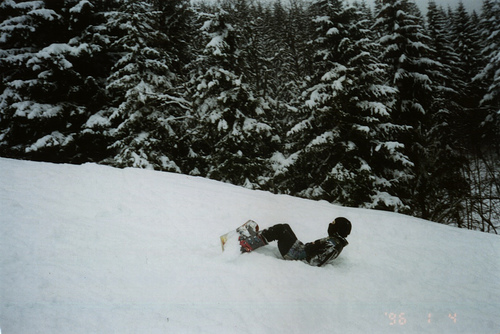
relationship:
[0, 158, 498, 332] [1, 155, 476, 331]
snow on hill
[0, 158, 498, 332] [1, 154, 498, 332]
snow on hill side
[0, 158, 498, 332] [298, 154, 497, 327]
snow on hill side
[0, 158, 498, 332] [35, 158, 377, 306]
snow on hillside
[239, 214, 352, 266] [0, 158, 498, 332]
person snowboarding in snow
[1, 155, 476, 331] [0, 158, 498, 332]
hill covered in snow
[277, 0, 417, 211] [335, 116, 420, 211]
tree covered in snow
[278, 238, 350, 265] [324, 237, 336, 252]
snow jacket covered in snow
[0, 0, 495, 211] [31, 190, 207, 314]
trees covered in snow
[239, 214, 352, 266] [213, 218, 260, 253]
person on board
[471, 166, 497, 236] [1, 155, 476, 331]
branches on hill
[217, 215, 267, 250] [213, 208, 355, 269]
skis on skier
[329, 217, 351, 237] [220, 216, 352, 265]
hat on skier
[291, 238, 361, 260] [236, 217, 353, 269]
snow jacket on skier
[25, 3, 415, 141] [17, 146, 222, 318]
evergreen trees bordering slope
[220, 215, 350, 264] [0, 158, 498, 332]
man in snow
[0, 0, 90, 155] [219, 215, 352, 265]
trees behind snowboarder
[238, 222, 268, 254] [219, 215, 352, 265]
boots of snowboarder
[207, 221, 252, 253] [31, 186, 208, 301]
board in snow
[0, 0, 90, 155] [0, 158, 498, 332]
trees in snow